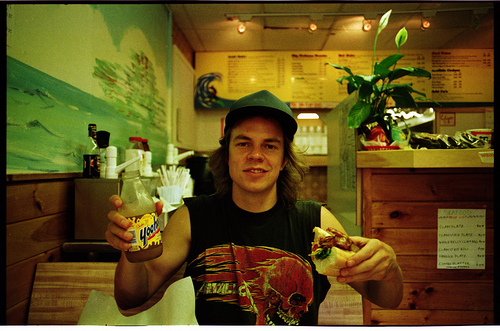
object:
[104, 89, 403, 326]
man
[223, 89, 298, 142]
hat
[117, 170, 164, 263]
bottle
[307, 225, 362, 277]
sandwich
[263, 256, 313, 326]
red skull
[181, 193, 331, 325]
shirt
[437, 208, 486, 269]
paper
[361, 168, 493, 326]
wall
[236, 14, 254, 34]
lights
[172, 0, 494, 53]
ceiling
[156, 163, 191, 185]
straws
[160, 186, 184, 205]
cup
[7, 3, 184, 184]
wall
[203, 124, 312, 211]
man's hair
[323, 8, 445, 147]
plant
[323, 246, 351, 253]
sauce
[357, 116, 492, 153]
items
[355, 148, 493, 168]
counter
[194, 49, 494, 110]
menu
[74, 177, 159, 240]
table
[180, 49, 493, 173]
wall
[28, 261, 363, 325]
bench